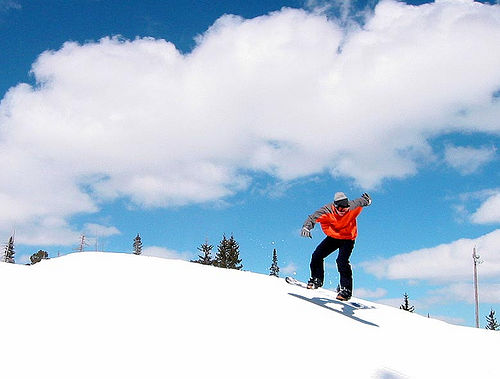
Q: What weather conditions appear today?
A: It is cloudy.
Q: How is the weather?
A: It is cloudy.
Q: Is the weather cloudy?
A: Yes, it is cloudy.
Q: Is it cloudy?
A: Yes, it is cloudy.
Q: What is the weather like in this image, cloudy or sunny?
A: It is cloudy.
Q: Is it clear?
A: No, it is cloudy.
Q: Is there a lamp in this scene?
A: No, there are no lamps.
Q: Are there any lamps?
A: No, there are no lamps.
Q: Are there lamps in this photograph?
A: No, there are no lamps.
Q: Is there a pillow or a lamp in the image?
A: No, there are no lamps or pillows.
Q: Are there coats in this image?
A: Yes, there is a coat.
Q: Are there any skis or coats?
A: Yes, there is a coat.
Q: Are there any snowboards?
A: Yes, there is a snowboard.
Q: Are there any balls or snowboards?
A: Yes, there is a snowboard.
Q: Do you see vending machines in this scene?
A: No, there are no vending machines.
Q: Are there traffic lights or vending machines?
A: No, there are no vending machines or traffic lights.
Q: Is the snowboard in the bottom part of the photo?
A: Yes, the snowboard is in the bottom of the image.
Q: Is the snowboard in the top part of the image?
A: No, the snowboard is in the bottom of the image.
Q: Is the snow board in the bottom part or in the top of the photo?
A: The snow board is in the bottom of the image.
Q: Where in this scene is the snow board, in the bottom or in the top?
A: The snow board is in the bottom of the image.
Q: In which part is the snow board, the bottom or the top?
A: The snow board is in the bottom of the image.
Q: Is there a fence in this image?
A: No, there are no fences.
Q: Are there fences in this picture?
A: No, there are no fences.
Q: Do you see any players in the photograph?
A: No, there are no players.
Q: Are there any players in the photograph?
A: No, there are no players.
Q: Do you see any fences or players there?
A: No, there are no players or fences.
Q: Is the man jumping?
A: Yes, the man is jumping.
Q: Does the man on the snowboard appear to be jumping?
A: Yes, the man is jumping.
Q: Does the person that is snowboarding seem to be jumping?
A: Yes, the man is jumping.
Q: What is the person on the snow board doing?
A: The man is jumping.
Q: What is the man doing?
A: The man is jumping.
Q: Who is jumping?
A: The man is jumping.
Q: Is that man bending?
A: No, the man is jumping.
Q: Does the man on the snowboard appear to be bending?
A: No, the man is jumping.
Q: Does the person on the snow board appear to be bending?
A: No, the man is jumping.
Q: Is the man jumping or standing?
A: The man is jumping.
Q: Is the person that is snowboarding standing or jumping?
A: The man is jumping.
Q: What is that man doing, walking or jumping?
A: The man is jumping.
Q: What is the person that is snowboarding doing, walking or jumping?
A: The man is jumping.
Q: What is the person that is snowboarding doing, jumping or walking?
A: The man is jumping.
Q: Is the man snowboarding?
A: Yes, the man is snowboarding.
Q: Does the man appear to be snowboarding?
A: Yes, the man is snowboarding.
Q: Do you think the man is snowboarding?
A: Yes, the man is snowboarding.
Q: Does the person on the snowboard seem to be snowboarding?
A: Yes, the man is snowboarding.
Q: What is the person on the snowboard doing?
A: The man is snowboarding.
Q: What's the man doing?
A: The man is snowboarding.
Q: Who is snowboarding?
A: The man is snowboarding.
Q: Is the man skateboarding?
A: No, the man is snowboarding.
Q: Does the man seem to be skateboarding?
A: No, the man is snowboarding.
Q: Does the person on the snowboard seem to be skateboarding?
A: No, the man is snowboarding.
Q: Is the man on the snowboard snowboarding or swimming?
A: The man is snowboarding.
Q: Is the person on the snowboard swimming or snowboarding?
A: The man is snowboarding.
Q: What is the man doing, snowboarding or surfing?
A: The man is snowboarding.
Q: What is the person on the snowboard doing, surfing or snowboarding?
A: The man is snowboarding.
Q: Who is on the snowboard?
A: The man is on the snow board.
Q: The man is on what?
A: The man is on the snowboard.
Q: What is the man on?
A: The man is on the snowboard.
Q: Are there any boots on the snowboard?
A: No, there is a man on the snowboard.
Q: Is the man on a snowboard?
A: Yes, the man is on a snowboard.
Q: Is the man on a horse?
A: No, the man is on a snowboard.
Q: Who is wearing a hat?
A: The man is wearing a hat.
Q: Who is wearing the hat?
A: The man is wearing a hat.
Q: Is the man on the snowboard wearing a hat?
A: Yes, the man is wearing a hat.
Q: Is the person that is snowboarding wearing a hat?
A: Yes, the man is wearing a hat.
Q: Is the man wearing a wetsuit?
A: No, the man is wearing a hat.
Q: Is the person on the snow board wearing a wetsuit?
A: No, the man is wearing a hat.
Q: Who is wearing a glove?
A: The man is wearing a glove.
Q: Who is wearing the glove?
A: The man is wearing a glove.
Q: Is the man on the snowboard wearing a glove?
A: Yes, the man is wearing a glove.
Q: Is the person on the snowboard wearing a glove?
A: Yes, the man is wearing a glove.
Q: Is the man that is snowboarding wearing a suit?
A: No, the man is wearing a glove.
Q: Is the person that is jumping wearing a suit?
A: No, the man is wearing a glove.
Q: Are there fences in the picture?
A: No, there are no fences.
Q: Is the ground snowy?
A: Yes, the ground is snowy.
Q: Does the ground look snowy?
A: Yes, the ground is snowy.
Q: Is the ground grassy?
A: No, the ground is snowy.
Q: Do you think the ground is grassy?
A: No, the ground is snowy.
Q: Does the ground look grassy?
A: No, the ground is snowy.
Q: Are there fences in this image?
A: No, there are no fences.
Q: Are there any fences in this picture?
A: No, there are no fences.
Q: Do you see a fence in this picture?
A: No, there are no fences.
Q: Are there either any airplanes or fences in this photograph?
A: No, there are no fences or airplanes.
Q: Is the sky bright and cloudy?
A: Yes, the sky is bright and cloudy.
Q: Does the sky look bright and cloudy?
A: Yes, the sky is bright and cloudy.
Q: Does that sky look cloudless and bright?
A: No, the sky is bright but cloudy.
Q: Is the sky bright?
A: Yes, the sky is bright.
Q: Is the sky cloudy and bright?
A: Yes, the sky is cloudy and bright.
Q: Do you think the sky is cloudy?
A: Yes, the sky is cloudy.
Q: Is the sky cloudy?
A: Yes, the sky is cloudy.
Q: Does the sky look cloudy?
A: Yes, the sky is cloudy.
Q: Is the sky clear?
A: No, the sky is cloudy.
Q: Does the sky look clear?
A: No, the sky is cloudy.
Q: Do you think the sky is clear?
A: No, the sky is cloudy.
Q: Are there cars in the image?
A: No, there are no cars.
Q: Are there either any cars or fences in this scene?
A: No, there are no cars or fences.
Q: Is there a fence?
A: No, there are no fences.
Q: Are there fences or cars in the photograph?
A: No, there are no fences or cars.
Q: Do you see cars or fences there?
A: No, there are no fences or cars.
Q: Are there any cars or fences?
A: No, there are no fences or cars.